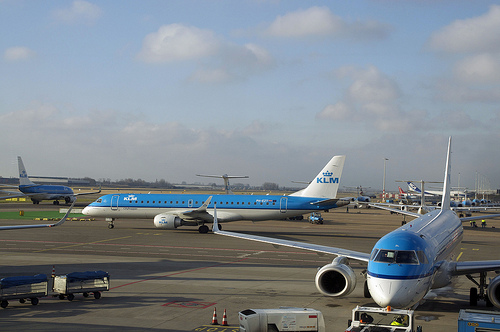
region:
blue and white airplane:
[81, 154, 351, 234]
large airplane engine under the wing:
[314, 261, 356, 297]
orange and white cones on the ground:
[209, 305, 229, 327]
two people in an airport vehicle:
[348, 303, 417, 328]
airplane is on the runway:
[15, 153, 79, 206]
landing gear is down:
[106, 220, 225, 234]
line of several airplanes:
[353, 180, 495, 217]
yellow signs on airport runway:
[6, 195, 26, 202]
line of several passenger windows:
[126, 195, 277, 207]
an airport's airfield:
[0, 183, 498, 330]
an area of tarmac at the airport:
[0, 203, 499, 330]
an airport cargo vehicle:
[0, 268, 110, 307]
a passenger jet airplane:
[211, 135, 498, 309]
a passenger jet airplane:
[82, 154, 349, 234]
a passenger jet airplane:
[0, 155, 101, 203]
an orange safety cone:
[209, 305, 219, 325]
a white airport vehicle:
[343, 303, 422, 330]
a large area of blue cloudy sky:
[0, 0, 499, 192]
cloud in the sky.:
[151, 38, 232, 56]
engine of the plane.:
[307, 265, 352, 300]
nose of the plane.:
[370, 290, 406, 303]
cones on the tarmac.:
[205, 304, 228, 326]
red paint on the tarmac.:
[157, 292, 209, 315]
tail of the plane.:
[327, 151, 351, 163]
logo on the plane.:
[313, 169, 339, 188]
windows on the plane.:
[142, 198, 169, 208]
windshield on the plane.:
[380, 250, 415, 261]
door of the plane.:
[108, 191, 120, 213]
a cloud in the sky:
[136, 23, 233, 69]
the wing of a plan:
[207, 210, 371, 263]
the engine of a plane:
[312, 255, 357, 300]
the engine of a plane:
[149, 209, 183, 231]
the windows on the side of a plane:
[125, 197, 274, 209]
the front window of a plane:
[373, 247, 417, 264]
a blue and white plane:
[82, 149, 352, 232]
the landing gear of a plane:
[464, 282, 489, 302]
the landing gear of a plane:
[103, 218, 119, 232]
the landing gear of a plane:
[194, 222, 210, 237]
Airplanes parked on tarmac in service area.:
[81, 136, 498, 308]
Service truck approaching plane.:
[341, 299, 428, 329]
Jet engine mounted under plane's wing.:
[314, 252, 356, 297]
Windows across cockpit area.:
[366, 241, 427, 266]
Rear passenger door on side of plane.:
[275, 193, 295, 217]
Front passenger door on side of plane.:
[108, 190, 125, 215]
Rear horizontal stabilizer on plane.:
[195, 166, 251, 181]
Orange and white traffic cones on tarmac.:
[206, 302, 233, 330]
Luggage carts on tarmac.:
[3, 265, 113, 315]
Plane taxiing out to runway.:
[5, 150, 105, 205]